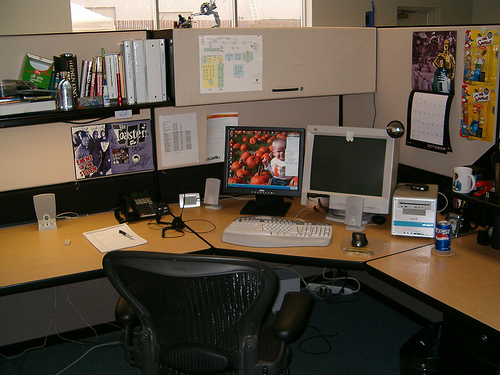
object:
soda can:
[435, 220, 452, 252]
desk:
[0, 188, 498, 343]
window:
[92, 7, 181, 27]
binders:
[120, 38, 168, 106]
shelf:
[0, 32, 171, 127]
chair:
[101, 249, 314, 374]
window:
[68, 2, 315, 32]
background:
[0, 5, 497, 224]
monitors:
[224, 125, 397, 199]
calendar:
[404, 30, 457, 154]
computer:
[222, 120, 438, 249]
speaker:
[33, 193, 57, 231]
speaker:
[204, 177, 223, 210]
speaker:
[345, 195, 366, 232]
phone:
[114, 189, 171, 223]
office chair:
[100, 248, 313, 373]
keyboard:
[222, 216, 334, 248]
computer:
[223, 125, 439, 249]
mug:
[453, 166, 476, 193]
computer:
[300, 120, 406, 232]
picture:
[453, 172, 462, 191]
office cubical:
[25, 15, 485, 366]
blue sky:
[101, 247, 312, 375]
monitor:
[222, 125, 305, 195]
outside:
[67, 0, 314, 31]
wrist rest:
[221, 231, 332, 248]